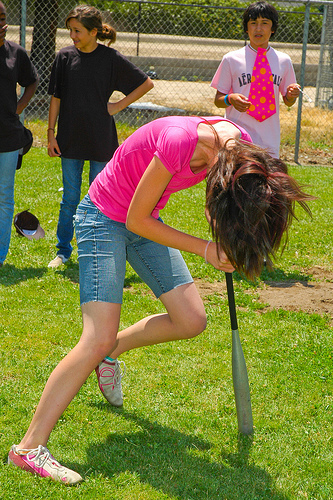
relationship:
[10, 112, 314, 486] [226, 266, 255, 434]
woman holding bat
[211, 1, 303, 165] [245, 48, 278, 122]
boy wearing tie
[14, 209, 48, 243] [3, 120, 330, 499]
cap lying on grass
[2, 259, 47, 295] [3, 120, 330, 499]
shadow cast onto grass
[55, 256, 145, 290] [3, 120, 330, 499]
shadow cast onto grass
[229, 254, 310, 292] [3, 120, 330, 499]
shadow cast onto grass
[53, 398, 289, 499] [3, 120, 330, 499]
shadow cast onto grass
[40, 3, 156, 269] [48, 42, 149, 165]
woman wearing shirt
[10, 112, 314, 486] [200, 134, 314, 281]
woman with hair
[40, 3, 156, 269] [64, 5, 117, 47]
woman with hair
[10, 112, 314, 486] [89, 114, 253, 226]
woman wearing shirt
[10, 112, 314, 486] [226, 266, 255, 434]
woman leaning on bat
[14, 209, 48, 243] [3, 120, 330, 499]
cap laying on grass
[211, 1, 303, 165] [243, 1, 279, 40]
boy with hair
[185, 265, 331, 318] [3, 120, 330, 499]
dirt in grass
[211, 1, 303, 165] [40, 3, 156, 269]
boy next to woman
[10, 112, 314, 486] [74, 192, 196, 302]
woman wearing shorts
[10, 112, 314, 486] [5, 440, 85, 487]
woman wearing shoe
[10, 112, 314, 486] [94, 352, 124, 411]
woman wearing shoe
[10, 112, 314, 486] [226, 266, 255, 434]
woman spinning on bat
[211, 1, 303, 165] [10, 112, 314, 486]
boy watching woman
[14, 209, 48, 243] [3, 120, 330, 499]
cap laying in grass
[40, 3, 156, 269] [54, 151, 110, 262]
woman wearing jeans